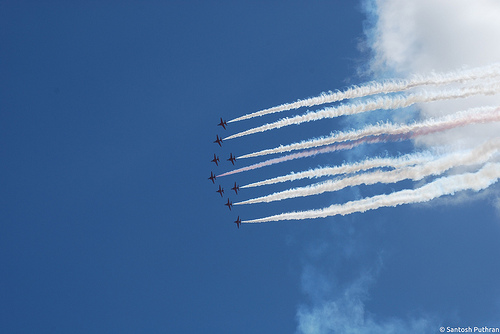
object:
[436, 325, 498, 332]
watermark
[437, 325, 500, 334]
name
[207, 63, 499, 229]
air show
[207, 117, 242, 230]
airplanes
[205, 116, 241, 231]
jet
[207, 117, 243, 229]
plane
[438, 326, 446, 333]
copyright label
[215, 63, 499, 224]
contrail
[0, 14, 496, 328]
sky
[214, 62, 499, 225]
smoke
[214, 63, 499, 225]
tail smoke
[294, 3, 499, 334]
cloud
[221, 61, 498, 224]
smoke line